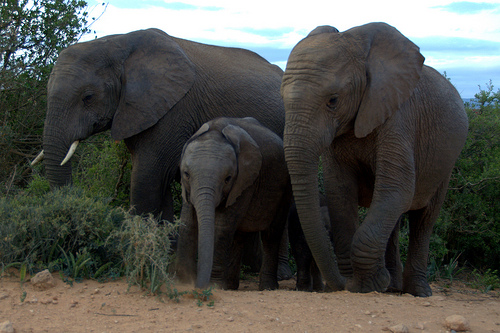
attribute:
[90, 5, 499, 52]
clouds — white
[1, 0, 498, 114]
sky — blue, white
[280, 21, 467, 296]
elephant — gray, large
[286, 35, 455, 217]
elephant — black, small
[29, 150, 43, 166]
tusk — white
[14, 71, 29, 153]
tree — old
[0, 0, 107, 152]
leaves — green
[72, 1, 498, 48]
clouds — white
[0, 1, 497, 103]
sky — blue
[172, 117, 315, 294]
baby elephant — gray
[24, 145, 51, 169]
tusk — ivory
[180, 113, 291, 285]
elephant — little, small